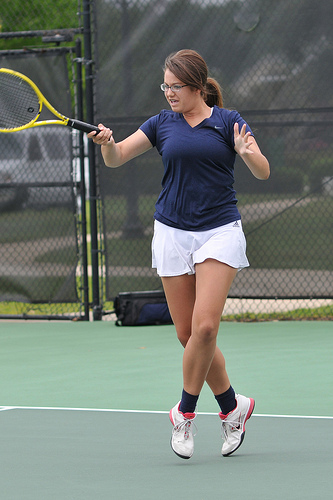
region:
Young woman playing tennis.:
[0, 46, 271, 457]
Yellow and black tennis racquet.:
[0, 64, 110, 137]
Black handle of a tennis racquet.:
[66, 116, 111, 139]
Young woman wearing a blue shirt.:
[136, 105, 251, 229]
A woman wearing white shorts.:
[148, 214, 248, 273]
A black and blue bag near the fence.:
[109, 287, 190, 325]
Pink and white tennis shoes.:
[166, 392, 252, 455]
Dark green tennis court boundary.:
[0, 406, 328, 495]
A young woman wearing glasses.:
[158, 81, 188, 89]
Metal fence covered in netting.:
[0, 0, 331, 498]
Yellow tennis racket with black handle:
[0, 66, 112, 144]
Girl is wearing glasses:
[158, 80, 195, 93]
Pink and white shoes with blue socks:
[163, 383, 260, 460]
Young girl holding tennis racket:
[1, 49, 261, 457]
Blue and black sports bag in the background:
[115, 286, 170, 329]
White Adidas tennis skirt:
[150, 208, 253, 283]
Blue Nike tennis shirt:
[141, 110, 252, 232]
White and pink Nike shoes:
[167, 400, 254, 458]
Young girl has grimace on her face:
[159, 58, 198, 114]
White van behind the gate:
[1, 123, 96, 205]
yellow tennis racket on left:
[5, 61, 107, 144]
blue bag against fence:
[110, 286, 175, 331]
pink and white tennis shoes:
[148, 391, 266, 461]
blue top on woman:
[126, 103, 257, 234]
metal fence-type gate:
[2, 41, 91, 325]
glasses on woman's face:
[152, 79, 197, 95]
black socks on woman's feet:
[172, 383, 242, 415]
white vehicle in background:
[0, 120, 76, 217]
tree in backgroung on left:
[4, 37, 87, 124]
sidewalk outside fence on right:
[222, 295, 330, 320]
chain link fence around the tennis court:
[93, 3, 330, 319]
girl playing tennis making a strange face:
[2, 47, 272, 463]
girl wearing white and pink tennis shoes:
[167, 384, 257, 462]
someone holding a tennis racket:
[0, 63, 115, 146]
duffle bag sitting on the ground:
[110, 287, 168, 328]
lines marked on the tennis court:
[0, 401, 330, 422]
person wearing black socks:
[176, 385, 238, 414]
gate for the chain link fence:
[1, 40, 89, 322]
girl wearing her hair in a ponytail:
[158, 47, 225, 112]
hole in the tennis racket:
[23, 104, 38, 113]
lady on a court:
[77, 40, 297, 193]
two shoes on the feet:
[135, 369, 274, 472]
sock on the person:
[176, 383, 203, 415]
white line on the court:
[87, 401, 126, 426]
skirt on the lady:
[130, 204, 278, 304]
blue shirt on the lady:
[112, 97, 274, 232]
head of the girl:
[132, 44, 227, 137]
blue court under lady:
[57, 433, 133, 492]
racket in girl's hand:
[0, 52, 119, 149]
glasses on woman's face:
[137, 46, 229, 125]